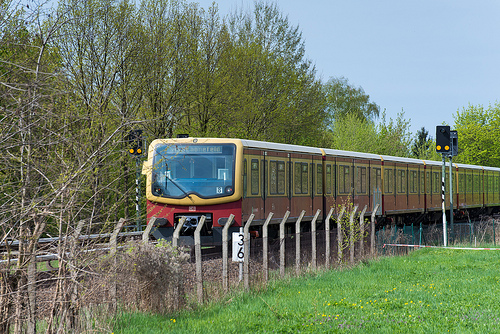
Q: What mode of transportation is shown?
A: Train.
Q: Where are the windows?
A: Train.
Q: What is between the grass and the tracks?
A: Fence.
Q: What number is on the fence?
A: 36.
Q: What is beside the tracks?
A: Gravel.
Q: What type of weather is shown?
A: Clear.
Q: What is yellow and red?
A: Train.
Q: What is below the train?
A: Tracks.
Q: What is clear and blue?
A: The sky.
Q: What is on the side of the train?
A: Windows.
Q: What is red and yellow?
A: The whole train.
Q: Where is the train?
A: The tracks.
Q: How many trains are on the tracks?
A: One.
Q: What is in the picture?
A: A train.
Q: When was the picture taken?
A: Daytime.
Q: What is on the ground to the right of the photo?
A: Grass.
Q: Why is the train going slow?
A: Caution rail lights.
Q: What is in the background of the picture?
A: Trees.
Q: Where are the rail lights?
A: Both sides of the train.